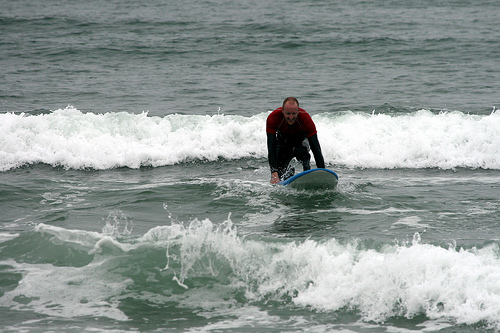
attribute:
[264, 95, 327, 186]
man — going bald, smiling, bald, kneeling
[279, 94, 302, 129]
head — bald, balding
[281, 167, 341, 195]
surfboard — white, blue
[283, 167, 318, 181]
stripe — blue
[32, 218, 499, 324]
wave — rippling, foamy, rolling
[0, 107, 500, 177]
wave — breaking, white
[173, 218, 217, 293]
cap — white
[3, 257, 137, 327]
foam — white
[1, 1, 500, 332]
water — blue grey, foamy, flat, dark, green grey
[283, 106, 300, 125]
face — smiling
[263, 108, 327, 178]
wetsuit — black, red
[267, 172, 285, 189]
hand — bare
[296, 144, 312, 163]
knee — bent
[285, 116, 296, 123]
mouth — smiling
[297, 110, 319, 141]
sleeve — short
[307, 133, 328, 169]
sleeve — long